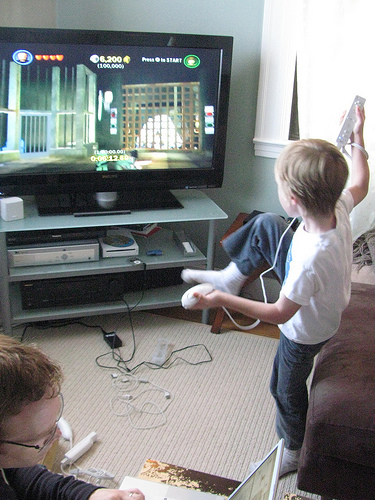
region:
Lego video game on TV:
[3, 33, 217, 177]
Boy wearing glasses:
[30, 379, 78, 459]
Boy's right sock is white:
[172, 255, 252, 302]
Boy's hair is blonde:
[274, 130, 350, 210]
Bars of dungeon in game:
[122, 84, 200, 153]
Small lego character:
[13, 51, 30, 62]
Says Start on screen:
[166, 56, 185, 67]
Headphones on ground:
[103, 363, 178, 428]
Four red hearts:
[33, 51, 68, 64]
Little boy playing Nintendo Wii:
[195, 81, 354, 346]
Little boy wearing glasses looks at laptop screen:
[0, 376, 265, 482]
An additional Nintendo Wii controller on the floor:
[53, 411, 116, 474]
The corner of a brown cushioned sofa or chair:
[301, 246, 358, 478]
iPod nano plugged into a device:
[124, 255, 146, 282]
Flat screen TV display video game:
[6, 45, 220, 215]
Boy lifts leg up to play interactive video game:
[225, 142, 316, 301]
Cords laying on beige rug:
[81, 325, 253, 445]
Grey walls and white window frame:
[240, 1, 370, 176]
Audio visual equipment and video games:
[4, 231, 163, 314]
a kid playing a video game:
[186, 87, 374, 474]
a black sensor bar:
[70, 212, 143, 216]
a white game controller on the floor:
[65, 430, 105, 465]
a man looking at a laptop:
[5, 363, 203, 498]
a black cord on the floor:
[78, 318, 120, 339]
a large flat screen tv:
[11, 27, 244, 218]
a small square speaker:
[1, 196, 29, 223]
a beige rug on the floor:
[193, 385, 253, 436]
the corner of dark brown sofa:
[330, 347, 362, 428]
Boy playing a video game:
[179, 88, 372, 483]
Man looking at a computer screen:
[1, 336, 289, 498]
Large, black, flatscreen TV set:
[1, 23, 235, 216]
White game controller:
[335, 94, 369, 154]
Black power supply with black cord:
[17, 321, 128, 353]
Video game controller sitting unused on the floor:
[55, 418, 118, 481]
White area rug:
[1, 313, 318, 489]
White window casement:
[248, 0, 324, 160]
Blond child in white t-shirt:
[270, 147, 363, 363]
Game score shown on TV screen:
[85, 50, 136, 72]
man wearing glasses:
[1, 326, 144, 499]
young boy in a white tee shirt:
[180, 91, 370, 478]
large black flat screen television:
[1, 21, 239, 221]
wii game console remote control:
[320, 95, 366, 158]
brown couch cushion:
[292, 270, 373, 496]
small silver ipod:
[123, 254, 148, 269]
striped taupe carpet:
[8, 304, 320, 499]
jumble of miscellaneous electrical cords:
[15, 266, 218, 436]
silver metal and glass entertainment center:
[0, 180, 233, 337]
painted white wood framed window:
[251, 1, 373, 164]